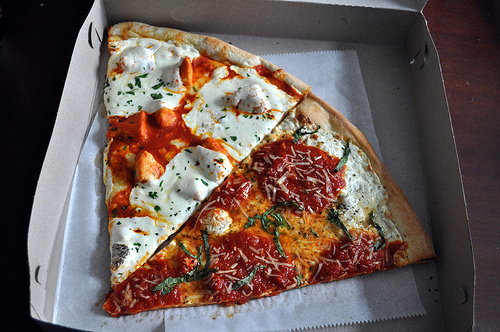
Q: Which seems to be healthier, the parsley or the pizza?
A: The parsley is healthier than the pizza.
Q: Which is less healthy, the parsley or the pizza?
A: The pizza is less healthy than the parsley.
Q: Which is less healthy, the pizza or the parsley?
A: The pizza is less healthy than the parsley.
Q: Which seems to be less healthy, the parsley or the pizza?
A: The pizza is less healthy than the parsley.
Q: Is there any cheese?
A: Yes, there is cheese.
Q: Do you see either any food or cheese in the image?
A: Yes, there is cheese.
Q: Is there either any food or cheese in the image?
A: Yes, there is cheese.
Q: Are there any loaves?
A: No, there are no loaves.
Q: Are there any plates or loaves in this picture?
A: No, there are no loaves or plates.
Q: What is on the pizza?
A: The cheese is on the pizza.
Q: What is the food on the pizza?
A: The food is cheese.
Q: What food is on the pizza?
A: The food is cheese.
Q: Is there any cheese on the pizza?
A: Yes, there is cheese on the pizza.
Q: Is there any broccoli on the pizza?
A: No, there is cheese on the pizza.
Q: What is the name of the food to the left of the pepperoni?
A: The food is cheese.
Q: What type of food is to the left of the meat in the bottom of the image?
A: The food is cheese.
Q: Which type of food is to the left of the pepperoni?
A: The food is cheese.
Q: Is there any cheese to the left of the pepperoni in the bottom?
A: Yes, there is cheese to the left of the pepperoni.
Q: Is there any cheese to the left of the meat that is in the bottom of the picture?
A: Yes, there is cheese to the left of the pepperoni.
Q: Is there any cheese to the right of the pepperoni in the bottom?
A: No, the cheese is to the left of the pepperoni.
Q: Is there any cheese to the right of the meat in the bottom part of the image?
A: No, the cheese is to the left of the pepperoni.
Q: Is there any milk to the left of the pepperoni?
A: No, there is cheese to the left of the pepperoni.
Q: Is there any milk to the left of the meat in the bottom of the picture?
A: No, there is cheese to the left of the pepperoni.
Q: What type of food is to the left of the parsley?
A: The food is cheese.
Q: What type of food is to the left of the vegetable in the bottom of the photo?
A: The food is cheese.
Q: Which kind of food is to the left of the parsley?
A: The food is cheese.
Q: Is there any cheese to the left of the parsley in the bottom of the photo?
A: Yes, there is cheese to the left of the parsley.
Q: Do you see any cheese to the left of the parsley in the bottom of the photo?
A: Yes, there is cheese to the left of the parsley.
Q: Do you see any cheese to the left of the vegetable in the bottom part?
A: Yes, there is cheese to the left of the parsley.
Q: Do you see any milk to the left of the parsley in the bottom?
A: No, there is cheese to the left of the parsley.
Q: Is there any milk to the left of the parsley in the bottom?
A: No, there is cheese to the left of the parsley.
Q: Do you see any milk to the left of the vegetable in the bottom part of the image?
A: No, there is cheese to the left of the parsley.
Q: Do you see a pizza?
A: Yes, there is a pizza.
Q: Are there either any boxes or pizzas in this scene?
A: Yes, there is a pizza.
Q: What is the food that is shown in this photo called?
A: The food is a pizza.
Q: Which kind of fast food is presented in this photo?
A: The fast food is a pizza.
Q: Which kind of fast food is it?
A: The food is a pizza.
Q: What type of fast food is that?
A: This is a pizza.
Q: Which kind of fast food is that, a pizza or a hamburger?
A: This is a pizza.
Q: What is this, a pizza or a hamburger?
A: This is a pizza.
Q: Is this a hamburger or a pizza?
A: This is a pizza.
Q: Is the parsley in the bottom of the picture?
A: Yes, the parsley is in the bottom of the image.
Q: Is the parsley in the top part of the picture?
A: No, the parsley is in the bottom of the image.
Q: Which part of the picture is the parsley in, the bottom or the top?
A: The parsley is in the bottom of the image.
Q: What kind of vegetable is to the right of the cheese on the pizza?
A: The vegetable is parsley.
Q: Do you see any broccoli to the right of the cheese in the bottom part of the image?
A: No, there is parsley to the right of the cheese.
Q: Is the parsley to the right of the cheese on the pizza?
A: Yes, the parsley is to the right of the cheese.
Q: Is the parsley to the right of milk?
A: No, the parsley is to the right of the cheese.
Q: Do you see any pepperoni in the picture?
A: Yes, there is pepperoni.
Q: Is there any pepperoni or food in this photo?
A: Yes, there is pepperoni.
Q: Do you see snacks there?
A: No, there are no snacks.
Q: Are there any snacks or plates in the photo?
A: No, there are no snacks or plates.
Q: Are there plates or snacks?
A: No, there are no snacks or plates.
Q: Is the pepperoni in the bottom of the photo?
A: Yes, the pepperoni is in the bottom of the image.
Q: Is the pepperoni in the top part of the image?
A: No, the pepperoni is in the bottom of the image.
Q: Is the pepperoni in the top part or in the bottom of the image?
A: The pepperoni is in the bottom of the image.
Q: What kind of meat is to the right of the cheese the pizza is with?
A: The meat is pepperoni.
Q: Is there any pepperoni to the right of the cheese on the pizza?
A: Yes, there is pepperoni to the right of the cheese.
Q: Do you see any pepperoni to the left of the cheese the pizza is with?
A: No, the pepperoni is to the right of the cheese.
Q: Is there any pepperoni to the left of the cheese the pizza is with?
A: No, the pepperoni is to the right of the cheese.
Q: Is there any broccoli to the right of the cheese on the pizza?
A: No, there is pepperoni to the right of the cheese.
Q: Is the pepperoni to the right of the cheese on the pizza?
A: Yes, the pepperoni is to the right of the cheese.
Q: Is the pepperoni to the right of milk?
A: No, the pepperoni is to the right of the cheese.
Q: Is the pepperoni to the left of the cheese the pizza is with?
A: No, the pepperoni is to the right of the cheese.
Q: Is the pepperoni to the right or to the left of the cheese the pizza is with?
A: The pepperoni is to the right of the cheese.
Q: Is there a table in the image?
A: Yes, there is a table.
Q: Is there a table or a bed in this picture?
A: Yes, there is a table.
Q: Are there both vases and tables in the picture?
A: No, there is a table but no vases.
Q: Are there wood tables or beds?
A: Yes, there is a wood table.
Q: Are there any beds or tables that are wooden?
A: Yes, the table is wooden.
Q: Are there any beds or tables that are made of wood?
A: Yes, the table is made of wood.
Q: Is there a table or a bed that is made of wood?
A: Yes, the table is made of wood.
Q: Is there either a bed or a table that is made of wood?
A: Yes, the table is made of wood.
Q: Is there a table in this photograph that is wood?
A: Yes, there is a wood table.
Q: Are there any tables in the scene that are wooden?
A: Yes, there is a table that is wooden.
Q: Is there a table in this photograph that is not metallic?
A: Yes, there is a wooden table.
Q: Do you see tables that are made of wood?
A: Yes, there is a table that is made of wood.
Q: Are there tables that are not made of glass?
A: Yes, there is a table that is made of wood.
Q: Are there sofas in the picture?
A: No, there are no sofas.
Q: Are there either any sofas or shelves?
A: No, there are no sofas or shelves.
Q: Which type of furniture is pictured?
A: The furniture is a table.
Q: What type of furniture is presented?
A: The furniture is a table.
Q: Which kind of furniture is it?
A: The piece of furniture is a table.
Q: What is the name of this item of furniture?
A: This is a table.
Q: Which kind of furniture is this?
A: This is a table.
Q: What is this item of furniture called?
A: This is a table.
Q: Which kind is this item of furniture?
A: This is a table.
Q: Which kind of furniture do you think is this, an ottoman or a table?
A: This is a table.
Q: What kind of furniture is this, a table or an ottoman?
A: This is a table.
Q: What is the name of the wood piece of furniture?
A: The piece of furniture is a table.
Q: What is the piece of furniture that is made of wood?
A: The piece of furniture is a table.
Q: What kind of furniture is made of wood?
A: The furniture is a table.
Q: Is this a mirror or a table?
A: This is a table.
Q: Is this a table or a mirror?
A: This is a table.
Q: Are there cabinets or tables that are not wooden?
A: No, there is a table but it is wooden.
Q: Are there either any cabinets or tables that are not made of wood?
A: No, there is a table but it is made of wood.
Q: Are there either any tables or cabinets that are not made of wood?
A: No, there is a table but it is made of wood.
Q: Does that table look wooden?
A: Yes, the table is wooden.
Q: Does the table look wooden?
A: Yes, the table is wooden.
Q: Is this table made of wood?
A: Yes, the table is made of wood.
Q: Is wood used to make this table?
A: Yes, the table is made of wood.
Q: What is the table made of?
A: The table is made of wood.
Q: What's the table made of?
A: The table is made of wood.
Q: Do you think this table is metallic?
A: No, the table is wooden.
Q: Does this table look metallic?
A: No, the table is wooden.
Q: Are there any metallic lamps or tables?
A: No, there is a table but it is wooden.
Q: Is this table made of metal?
A: No, the table is made of wood.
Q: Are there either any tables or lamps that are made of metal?
A: No, there is a table but it is made of wood.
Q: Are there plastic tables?
A: No, there is a table but it is made of wood.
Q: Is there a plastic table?
A: No, there is a table but it is made of wood.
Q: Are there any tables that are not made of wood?
A: No, there is a table but it is made of wood.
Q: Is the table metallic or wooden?
A: The table is wooden.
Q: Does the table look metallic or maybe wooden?
A: The table is wooden.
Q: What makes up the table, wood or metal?
A: The table is made of wood.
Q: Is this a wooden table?
A: Yes, this is a wooden table.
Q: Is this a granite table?
A: No, this is a wooden table.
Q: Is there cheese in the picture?
A: Yes, there is cheese.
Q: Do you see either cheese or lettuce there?
A: Yes, there is cheese.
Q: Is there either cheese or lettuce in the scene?
A: Yes, there is cheese.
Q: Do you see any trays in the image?
A: No, there are no trays.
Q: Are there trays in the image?
A: No, there are no trays.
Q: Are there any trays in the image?
A: No, there are no trays.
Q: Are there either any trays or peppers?
A: No, there are no trays or peppers.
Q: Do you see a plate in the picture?
A: No, there are no plates.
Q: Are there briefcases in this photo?
A: No, there are no briefcases.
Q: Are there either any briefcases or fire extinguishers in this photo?
A: No, there are no briefcases or fire extinguishers.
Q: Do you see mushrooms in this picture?
A: No, there are no mushrooms.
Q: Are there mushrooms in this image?
A: No, there are no mushrooms.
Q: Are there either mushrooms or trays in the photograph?
A: No, there are no mushrooms or trays.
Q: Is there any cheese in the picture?
A: Yes, there is cheese.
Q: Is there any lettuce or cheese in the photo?
A: Yes, there is cheese.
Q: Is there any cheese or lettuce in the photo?
A: Yes, there is cheese.